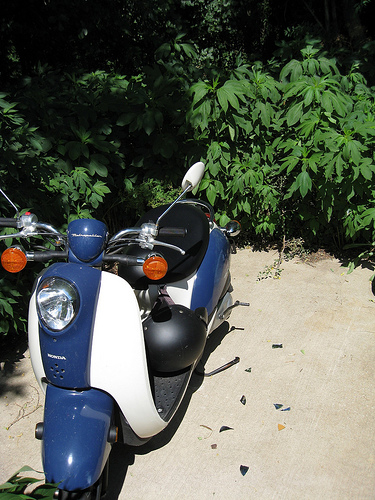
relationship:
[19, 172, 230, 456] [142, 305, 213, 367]
bike near helmet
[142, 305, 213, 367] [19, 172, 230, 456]
helmet on bike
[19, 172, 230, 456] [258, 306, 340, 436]
bike on road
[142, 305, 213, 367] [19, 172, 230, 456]
helmet near bike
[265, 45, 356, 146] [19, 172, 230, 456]
trees behind bike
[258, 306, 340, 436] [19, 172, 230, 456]
road below bike